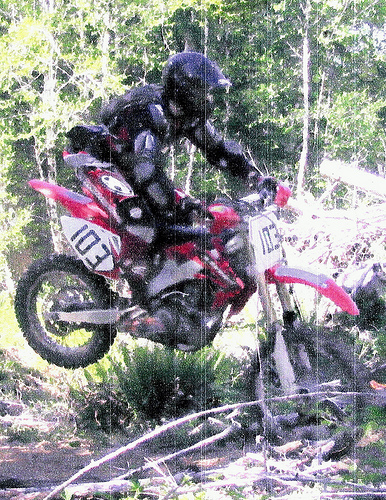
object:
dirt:
[0, 426, 242, 486]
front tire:
[244, 325, 373, 457]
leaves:
[3, 2, 384, 150]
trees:
[0, 0, 384, 294]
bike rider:
[65, 49, 279, 333]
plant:
[87, 330, 240, 414]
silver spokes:
[29, 308, 54, 325]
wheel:
[13, 254, 117, 370]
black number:
[70, 224, 114, 275]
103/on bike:
[14, 149, 370, 461]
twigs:
[208, 442, 310, 492]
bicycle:
[15, 145, 369, 460]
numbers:
[256, 222, 283, 255]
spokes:
[38, 277, 64, 304]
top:
[65, 83, 252, 212]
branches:
[281, 36, 301, 60]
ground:
[2, 291, 373, 494]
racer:
[16, 49, 372, 461]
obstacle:
[69, 382, 310, 474]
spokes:
[266, 377, 346, 395]